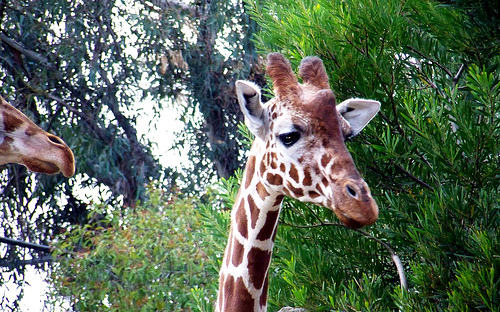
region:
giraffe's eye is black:
[274, 125, 312, 157]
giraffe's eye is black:
[262, 115, 301, 161]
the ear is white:
[211, 72, 277, 159]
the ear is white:
[334, 96, 379, 153]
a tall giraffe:
[75, 19, 430, 309]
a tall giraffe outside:
[129, 48, 435, 308]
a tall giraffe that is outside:
[179, 41, 451, 307]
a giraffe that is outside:
[157, 31, 419, 311]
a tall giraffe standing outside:
[190, 55, 499, 304]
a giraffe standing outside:
[132, 37, 411, 304]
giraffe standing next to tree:
[144, 26, 419, 311]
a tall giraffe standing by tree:
[112, 29, 411, 306]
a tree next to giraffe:
[84, 41, 459, 309]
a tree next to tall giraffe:
[192, 26, 439, 293]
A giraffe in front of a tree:
[183, 47, 394, 308]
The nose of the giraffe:
[337, 177, 372, 208]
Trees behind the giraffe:
[403, 35, 495, 310]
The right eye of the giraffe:
[276, 123, 305, 148]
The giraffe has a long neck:
[229, 206, 272, 310]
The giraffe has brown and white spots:
[273, 168, 315, 185]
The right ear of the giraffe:
[223, 75, 267, 126]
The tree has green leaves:
[433, 60, 476, 254]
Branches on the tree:
[386, 250, 411, 288]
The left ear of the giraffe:
[336, 95, 383, 130]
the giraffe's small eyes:
[282, 119, 359, 149]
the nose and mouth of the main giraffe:
[330, 174, 385, 237]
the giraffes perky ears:
[222, 71, 383, 138]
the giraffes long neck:
[227, 152, 277, 307]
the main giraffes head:
[230, 36, 372, 309]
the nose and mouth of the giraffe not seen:
[6, 97, 83, 198]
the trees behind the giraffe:
[39, 23, 476, 282]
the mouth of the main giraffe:
[331, 206, 388, 232]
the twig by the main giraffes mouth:
[305, 209, 418, 296]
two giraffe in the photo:
[7, 79, 381, 289]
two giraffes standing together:
[5, 23, 415, 307]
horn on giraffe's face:
[305, 79, 340, 126]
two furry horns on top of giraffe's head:
[269, 43, 326, 100]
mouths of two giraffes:
[19, 134, 378, 243]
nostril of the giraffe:
[341, 183, 375, 210]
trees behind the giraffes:
[14, 5, 486, 300]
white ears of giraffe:
[229, 79, 380, 144]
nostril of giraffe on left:
[40, 130, 65, 145]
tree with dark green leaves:
[2, 8, 219, 235]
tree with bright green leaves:
[117, 15, 482, 310]